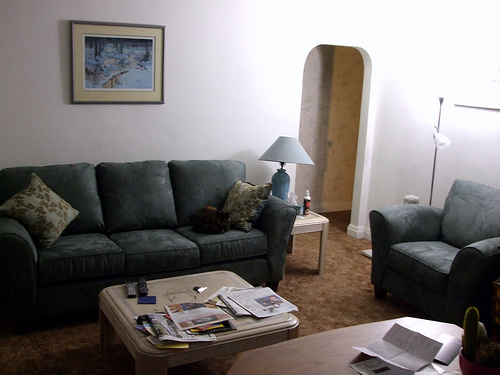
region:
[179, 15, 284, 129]
The color of the wall is white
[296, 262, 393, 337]
The floor has brown carpet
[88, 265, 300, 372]
The table in the living room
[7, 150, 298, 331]
The couch in the living room is gray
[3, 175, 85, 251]
The pillow on the couch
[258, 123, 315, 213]
The lamp on the table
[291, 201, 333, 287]
The end table against the wall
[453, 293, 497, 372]
A plant on the table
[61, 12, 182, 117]
A picture hanging on the wall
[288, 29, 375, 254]
The door way to another room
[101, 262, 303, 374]
The coffee table in the living room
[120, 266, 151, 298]
The remotes on the table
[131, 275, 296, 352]
The newspaper on the table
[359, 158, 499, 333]
The chair against the wall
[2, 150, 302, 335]
The long couch is the color gray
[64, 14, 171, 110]
The picture on the wall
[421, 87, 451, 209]
The lamp in the room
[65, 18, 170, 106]
a large picture frame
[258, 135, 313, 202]
a blue table lamp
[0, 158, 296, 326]
a large green sofa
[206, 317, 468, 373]
part of a brown table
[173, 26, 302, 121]
part of a painted white wall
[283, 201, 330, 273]
part of a side table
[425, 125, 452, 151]
a white lamp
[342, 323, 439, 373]
a sheet of paper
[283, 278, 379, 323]
a portion of brown carpet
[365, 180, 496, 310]
a green living room chair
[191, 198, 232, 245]
cat laying on couch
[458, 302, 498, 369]
cactus in a red pot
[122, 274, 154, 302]
remotes are on coffee table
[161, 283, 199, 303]
glasses on top of table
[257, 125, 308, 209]
blue lamp with white shade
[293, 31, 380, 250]
arched doorway to hall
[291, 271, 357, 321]
brown carpet on floor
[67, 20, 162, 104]
picture hanging on wall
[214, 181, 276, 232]
throw pillow beside cat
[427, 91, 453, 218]
stand lamp beside chair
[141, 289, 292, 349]
newspapers on a square table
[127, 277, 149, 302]
remotes on the table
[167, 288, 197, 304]
a pair of reading glasses on the square table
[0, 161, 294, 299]
a gray couch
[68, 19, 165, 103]
framed hard above the couch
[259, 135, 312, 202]
a lamp on the end table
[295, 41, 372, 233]
a doorway with curved top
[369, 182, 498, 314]
a gray chair on the right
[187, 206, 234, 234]
a black cat laying on the couch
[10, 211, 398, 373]
brown carpet in the room